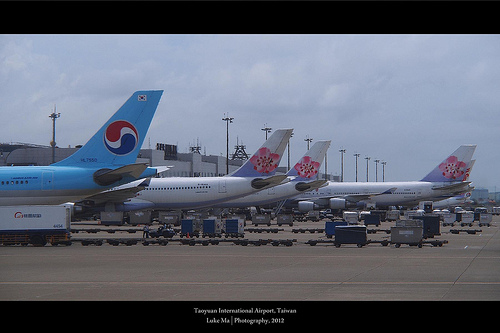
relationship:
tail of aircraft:
[60, 80, 170, 178] [4, 77, 191, 260]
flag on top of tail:
[126, 86, 156, 109] [60, 80, 170, 178]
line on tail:
[0, 281, 500, 285] [68, 79, 168, 168]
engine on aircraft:
[288, 195, 318, 213] [248, 157, 442, 229]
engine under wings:
[288, 195, 318, 213] [78, 94, 180, 193]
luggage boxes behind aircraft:
[333, 195, 458, 256] [184, 171, 316, 213]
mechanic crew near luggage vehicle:
[141, 208, 198, 245] [156, 220, 220, 242]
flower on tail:
[250, 147, 280, 175] [233, 117, 296, 182]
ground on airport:
[2, 208, 497, 299] [50, 83, 487, 261]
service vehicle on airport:
[1, 205, 72, 246] [1, 87, 498, 301]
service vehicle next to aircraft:
[1, 205, 72, 246] [4, 86, 166, 216]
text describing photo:
[190, 303, 302, 328] [0, 33, 498, 301]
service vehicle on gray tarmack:
[1, 201, 76, 251] [3, 235, 108, 265]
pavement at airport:
[21, 249, 472, 298] [1, 87, 498, 301]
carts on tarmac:
[179, 219, 246, 238] [0, 247, 472, 284]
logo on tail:
[103, 117, 140, 154] [56, 87, 166, 164]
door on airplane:
[215, 179, 227, 200] [0, 88, 157, 239]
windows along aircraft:
[131, 177, 209, 198] [0, 90, 174, 247]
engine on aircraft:
[83, 189, 161, 237] [0, 90, 174, 247]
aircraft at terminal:
[0, 90, 174, 247] [37, 68, 479, 291]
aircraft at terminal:
[61, 128, 294, 227] [37, 68, 479, 291]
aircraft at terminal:
[212, 140, 330, 227] [37, 68, 479, 291]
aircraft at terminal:
[263, 144, 478, 222] [37, 68, 479, 291]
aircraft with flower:
[61, 128, 294, 227] [440, 156, 465, 178]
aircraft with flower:
[212, 140, 330, 227] [292, 155, 320, 176]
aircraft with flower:
[263, 144, 478, 222] [249, 147, 279, 174]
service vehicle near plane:
[1, 205, 72, 246] [3, 76, 162, 251]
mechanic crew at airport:
[142, 223, 149, 239] [6, 26, 496, 313]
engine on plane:
[297, 200, 324, 211] [7, 79, 484, 256]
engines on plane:
[327, 187, 354, 206] [315, 152, 437, 232]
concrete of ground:
[260, 247, 395, 288] [2, 208, 497, 299]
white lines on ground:
[453, 240, 482, 252] [2, 208, 497, 299]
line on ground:
[276, 244, 388, 302] [80, 235, 473, 306]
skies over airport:
[1, 35, 498, 192] [1, 87, 498, 301]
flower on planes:
[244, 148, 288, 180] [188, 117, 292, 228]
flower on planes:
[290, 139, 318, 176] [284, 131, 344, 187]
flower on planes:
[428, 140, 466, 180] [348, 124, 476, 214]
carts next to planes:
[184, 199, 442, 269] [23, 76, 498, 216]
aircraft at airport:
[0, 90, 174, 247] [0, 34, 500, 301]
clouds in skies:
[0, 34, 500, 189] [1, 35, 498, 192]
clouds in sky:
[0, 34, 500, 189] [1, 34, 499, 189]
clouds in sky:
[0, 34, 500, 189] [80, 46, 498, 193]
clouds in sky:
[182, 50, 453, 138] [215, 58, 414, 151]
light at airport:
[221, 115, 233, 173] [30, 73, 465, 285]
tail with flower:
[239, 121, 289, 181] [251, 142, 273, 172]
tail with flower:
[297, 140, 331, 185] [294, 157, 319, 177]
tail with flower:
[425, 140, 475, 187] [442, 154, 465, 179]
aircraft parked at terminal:
[0, 90, 174, 247] [3, 136, 348, 218]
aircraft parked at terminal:
[61, 128, 294, 227] [3, 136, 348, 218]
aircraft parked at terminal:
[212, 140, 330, 227] [3, 136, 348, 218]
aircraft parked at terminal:
[263, 144, 478, 222] [3, 136, 348, 218]